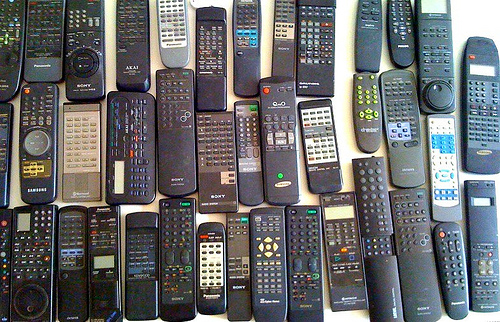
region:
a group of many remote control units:
[4, 10, 497, 319]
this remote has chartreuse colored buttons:
[341, 68, 387, 153]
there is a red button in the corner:
[252, 72, 309, 203]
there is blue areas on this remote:
[425, 114, 467, 221]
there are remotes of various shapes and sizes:
[24, 30, 466, 277]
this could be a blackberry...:
[106, 84, 160, 215]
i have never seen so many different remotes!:
[7, 10, 482, 320]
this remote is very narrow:
[233, 99, 270, 208]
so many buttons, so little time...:
[102, 80, 169, 207]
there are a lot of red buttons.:
[9, 70, 488, 242]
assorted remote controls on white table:
[66, 14, 483, 299]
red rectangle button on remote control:
[198, 228, 215, 245]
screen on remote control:
[468, 57, 498, 74]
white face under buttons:
[305, 101, 335, 164]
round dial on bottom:
[421, 74, 456, 114]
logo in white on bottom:
[121, 60, 144, 77]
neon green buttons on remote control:
[354, 77, 379, 127]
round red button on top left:
[260, 84, 272, 96]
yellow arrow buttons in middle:
[252, 235, 284, 261]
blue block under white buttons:
[425, 182, 460, 204]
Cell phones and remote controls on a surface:
[0, 3, 497, 313]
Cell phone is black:
[84, 199, 128, 319]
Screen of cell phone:
[86, 251, 118, 274]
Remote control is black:
[245, 204, 294, 319]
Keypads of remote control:
[251, 214, 286, 299]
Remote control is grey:
[421, 110, 470, 222]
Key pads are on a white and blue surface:
[426, 115, 459, 206]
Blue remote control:
[13, 80, 64, 210]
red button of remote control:
[19, 80, 36, 100]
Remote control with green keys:
[351, 68, 388, 154]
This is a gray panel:
[17, 210, 31, 234]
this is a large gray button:
[20, 126, 55, 158]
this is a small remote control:
[189, 210, 235, 320]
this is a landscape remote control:
[92, 90, 167, 207]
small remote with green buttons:
[346, 67, 396, 165]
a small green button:
[181, 263, 195, 273]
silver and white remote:
[53, 88, 110, 206]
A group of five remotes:
[166, 187, 329, 319]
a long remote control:
[343, 146, 404, 320]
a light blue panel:
[428, 135, 460, 156]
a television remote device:
[457, 34, 497, 175]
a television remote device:
[414, 0, 456, 112]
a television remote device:
[380, 69, 422, 186]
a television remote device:
[392, 188, 430, 320]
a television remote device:
[321, 192, 358, 311]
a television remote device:
[286, 203, 321, 320]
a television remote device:
[249, 206, 289, 318]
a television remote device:
[260, 67, 300, 201]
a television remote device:
[160, 196, 197, 320]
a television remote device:
[18, 72, 58, 207]